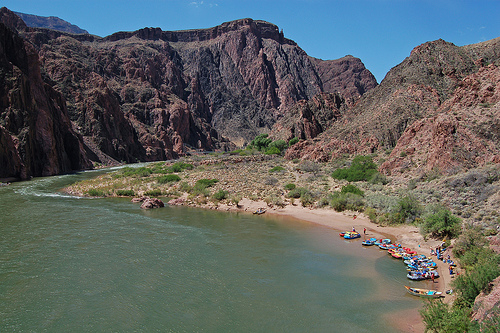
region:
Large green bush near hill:
[335, 155, 385, 185]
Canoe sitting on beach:
[407, 285, 442, 296]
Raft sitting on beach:
[409, 269, 438, 278]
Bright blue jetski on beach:
[365, 236, 375, 246]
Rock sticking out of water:
[142, 198, 163, 209]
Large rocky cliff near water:
[2, 4, 372, 180]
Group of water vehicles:
[338, 229, 443, 296]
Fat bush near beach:
[422, 209, 466, 237]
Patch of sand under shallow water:
[390, 307, 428, 332]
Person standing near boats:
[362, 228, 367, 238]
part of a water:
[224, 263, 262, 327]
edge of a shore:
[293, 198, 325, 250]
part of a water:
[263, 241, 281, 293]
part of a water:
[227, 220, 259, 262]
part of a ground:
[406, 150, 437, 219]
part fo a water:
[244, 243, 271, 280]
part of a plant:
[288, 165, 307, 199]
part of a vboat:
[413, 281, 428, 310]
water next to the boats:
[100, 245, 192, 296]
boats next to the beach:
[343, 213, 434, 316]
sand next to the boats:
[418, 248, 431, 257]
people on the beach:
[432, 240, 455, 268]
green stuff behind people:
[339, 158, 381, 187]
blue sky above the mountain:
[351, 7, 395, 44]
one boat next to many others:
[401, 284, 442, 310]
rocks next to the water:
[113, 100, 164, 147]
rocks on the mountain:
[206, 53, 270, 90]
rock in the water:
[141, 193, 168, 221]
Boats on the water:
[340, 228, 457, 308]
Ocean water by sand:
[8, 190, 388, 325]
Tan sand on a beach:
[253, 180, 495, 320]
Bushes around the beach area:
[96, 136, 456, 228]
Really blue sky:
[15, 4, 499, 61]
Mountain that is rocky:
[9, 10, 497, 167]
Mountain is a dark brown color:
[3, 13, 498, 173]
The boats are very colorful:
[345, 231, 455, 306]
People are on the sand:
[347, 212, 472, 302]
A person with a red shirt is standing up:
[356, 223, 373, 238]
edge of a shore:
[274, 192, 313, 233]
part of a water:
[241, 245, 267, 272]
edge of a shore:
[281, 192, 315, 241]